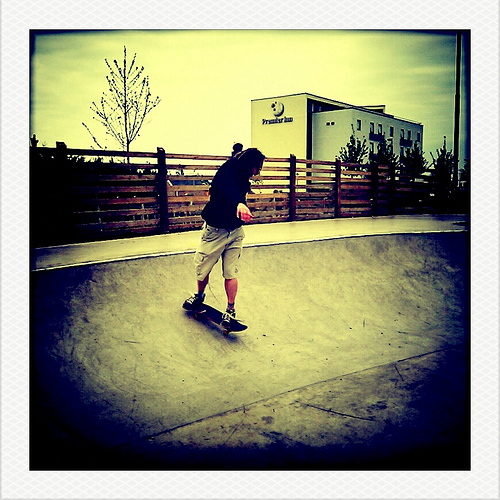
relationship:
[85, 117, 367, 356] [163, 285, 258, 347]
man on skateboard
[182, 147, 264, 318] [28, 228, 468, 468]
man skateboarding on ramp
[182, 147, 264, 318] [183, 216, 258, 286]
man wearing shorts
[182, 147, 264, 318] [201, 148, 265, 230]
man wearing a hoodie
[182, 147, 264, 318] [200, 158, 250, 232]
man wearing a hoodie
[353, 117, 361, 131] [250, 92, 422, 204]
window on a building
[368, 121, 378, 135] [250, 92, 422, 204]
window on a building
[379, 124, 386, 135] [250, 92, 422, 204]
window on a building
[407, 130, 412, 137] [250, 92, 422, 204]
window on a building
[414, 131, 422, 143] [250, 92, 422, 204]
window on a building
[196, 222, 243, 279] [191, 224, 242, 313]
shorts on legs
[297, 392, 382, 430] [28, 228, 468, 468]
mark on ramp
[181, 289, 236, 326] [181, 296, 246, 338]
feet on skateboard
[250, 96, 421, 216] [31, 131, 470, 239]
building behind fence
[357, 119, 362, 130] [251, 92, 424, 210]
window on side of building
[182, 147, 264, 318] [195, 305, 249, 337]
man riding a skateboard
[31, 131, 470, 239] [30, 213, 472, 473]
fence near a park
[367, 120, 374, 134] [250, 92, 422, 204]
window on building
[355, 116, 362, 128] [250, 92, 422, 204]
window on building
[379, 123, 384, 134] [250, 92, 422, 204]
window on building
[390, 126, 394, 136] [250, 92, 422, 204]
window on building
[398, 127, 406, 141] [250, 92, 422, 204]
window on building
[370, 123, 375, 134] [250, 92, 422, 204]
window on building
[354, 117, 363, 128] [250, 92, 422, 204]
window on building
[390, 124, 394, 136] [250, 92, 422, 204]
window on building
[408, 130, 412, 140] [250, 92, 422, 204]
window on building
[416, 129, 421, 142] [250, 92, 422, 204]
window on building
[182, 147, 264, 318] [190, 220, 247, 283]
man wearing shorts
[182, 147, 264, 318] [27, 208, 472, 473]
man on a ramp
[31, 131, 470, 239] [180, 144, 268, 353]
fence behind man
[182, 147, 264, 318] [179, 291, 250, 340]
man riding a skateboard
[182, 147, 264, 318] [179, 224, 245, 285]
man wearing shorts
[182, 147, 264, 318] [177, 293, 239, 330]
man wearing shoes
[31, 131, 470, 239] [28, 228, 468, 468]
fence along top of ramp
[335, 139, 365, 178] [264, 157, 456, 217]
tree behind fence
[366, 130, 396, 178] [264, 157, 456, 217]
tree behind fence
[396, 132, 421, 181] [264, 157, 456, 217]
tree behind fence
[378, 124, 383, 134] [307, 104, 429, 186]
window on a building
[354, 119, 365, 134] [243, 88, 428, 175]
window on a building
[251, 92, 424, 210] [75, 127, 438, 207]
building in background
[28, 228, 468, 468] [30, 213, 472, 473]
ramp at park